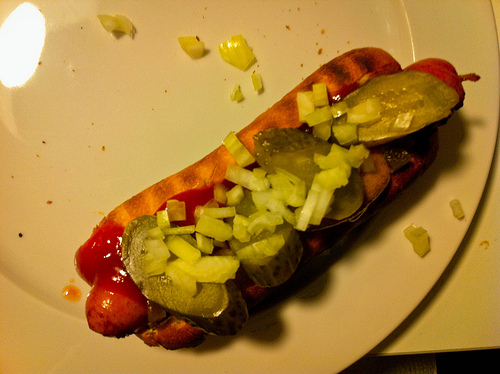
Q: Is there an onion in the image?
A: Yes, there is an onion.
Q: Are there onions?
A: Yes, there is an onion.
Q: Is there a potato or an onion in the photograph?
A: Yes, there is an onion.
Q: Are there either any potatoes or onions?
A: Yes, there is an onion.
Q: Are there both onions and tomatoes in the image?
A: No, there is an onion but no tomatoes.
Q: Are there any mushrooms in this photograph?
A: No, there are no mushrooms.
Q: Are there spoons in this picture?
A: No, there are no spoons.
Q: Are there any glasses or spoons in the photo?
A: No, there are no spoons or glasses.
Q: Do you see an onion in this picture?
A: Yes, there are onions.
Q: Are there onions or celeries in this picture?
A: Yes, there are onions.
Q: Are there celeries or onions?
A: Yes, there are onions.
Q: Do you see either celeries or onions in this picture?
A: Yes, there are onions.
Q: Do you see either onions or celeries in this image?
A: Yes, there are onions.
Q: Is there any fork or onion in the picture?
A: Yes, there are onions.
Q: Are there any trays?
A: No, there are no trays.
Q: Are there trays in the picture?
A: No, there are no trays.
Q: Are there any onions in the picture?
A: Yes, there is an onion.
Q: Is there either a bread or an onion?
A: Yes, there is an onion.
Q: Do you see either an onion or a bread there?
A: Yes, there is an onion.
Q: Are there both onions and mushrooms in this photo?
A: No, there is an onion but no mushrooms.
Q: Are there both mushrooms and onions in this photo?
A: No, there is an onion but no mushrooms.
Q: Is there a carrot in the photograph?
A: No, there are no carrots.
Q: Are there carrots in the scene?
A: No, there are no carrots.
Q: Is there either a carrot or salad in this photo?
A: No, there are no carrots or salad.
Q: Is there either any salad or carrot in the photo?
A: No, there are no carrots or salad.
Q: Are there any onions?
A: Yes, there is an onion.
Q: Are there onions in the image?
A: Yes, there is an onion.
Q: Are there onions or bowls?
A: Yes, there is an onion.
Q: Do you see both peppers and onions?
A: No, there is an onion but no peppers.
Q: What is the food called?
A: The food is a bun.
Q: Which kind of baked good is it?
A: The food is a bun.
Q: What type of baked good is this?
A: That is a bun.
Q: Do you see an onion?
A: Yes, there is an onion.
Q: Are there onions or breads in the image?
A: Yes, there is an onion.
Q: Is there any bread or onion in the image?
A: Yes, there is an onion.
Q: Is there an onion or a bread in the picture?
A: Yes, there is an onion.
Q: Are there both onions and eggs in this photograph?
A: No, there is an onion but no eggs.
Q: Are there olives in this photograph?
A: No, there are no olives.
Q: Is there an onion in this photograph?
A: Yes, there is an onion.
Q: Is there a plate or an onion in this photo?
A: Yes, there is an onion.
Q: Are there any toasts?
A: No, there are no toasts.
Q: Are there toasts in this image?
A: No, there are no toasts.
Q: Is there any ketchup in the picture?
A: Yes, there is ketchup.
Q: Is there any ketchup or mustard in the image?
A: Yes, there is ketchup.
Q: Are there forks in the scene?
A: No, there are no forks.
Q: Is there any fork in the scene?
A: No, there are no forks.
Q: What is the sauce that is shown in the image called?
A: The sauce is ketchup.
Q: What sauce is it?
A: The sauce is ketchup.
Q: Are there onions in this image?
A: Yes, there is an onion.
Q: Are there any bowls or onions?
A: Yes, there is an onion.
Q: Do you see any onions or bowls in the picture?
A: Yes, there is an onion.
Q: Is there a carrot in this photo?
A: No, there are no carrots.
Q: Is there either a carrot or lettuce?
A: No, there are no carrots or lettuce.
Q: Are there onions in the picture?
A: Yes, there is an onion.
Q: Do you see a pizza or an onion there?
A: Yes, there is an onion.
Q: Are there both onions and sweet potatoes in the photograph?
A: No, there is an onion but no sweet potatoes.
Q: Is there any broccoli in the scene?
A: No, there is no broccoli.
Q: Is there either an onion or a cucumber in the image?
A: Yes, there is an onion.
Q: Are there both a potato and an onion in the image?
A: No, there is an onion but no potatoes.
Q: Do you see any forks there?
A: No, there are no forks.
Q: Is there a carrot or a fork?
A: No, there are no forks or carrots.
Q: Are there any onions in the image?
A: Yes, there is an onion.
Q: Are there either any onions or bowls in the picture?
A: Yes, there is an onion.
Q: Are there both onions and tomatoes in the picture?
A: No, there is an onion but no tomatoes.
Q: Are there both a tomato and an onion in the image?
A: No, there is an onion but no tomatoes.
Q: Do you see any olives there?
A: No, there are no olives.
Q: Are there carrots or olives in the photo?
A: No, there are no olives or carrots.